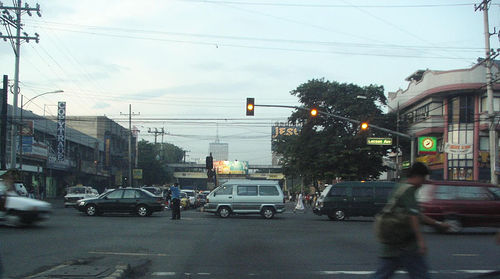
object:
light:
[246, 98, 255, 116]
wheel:
[85, 205, 98, 217]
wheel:
[137, 205, 150, 217]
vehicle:
[76, 187, 166, 216]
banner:
[445, 142, 473, 154]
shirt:
[378, 182, 422, 258]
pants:
[368, 244, 432, 279]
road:
[0, 194, 500, 279]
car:
[202, 180, 284, 220]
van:
[201, 180, 287, 219]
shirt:
[169, 186, 180, 199]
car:
[413, 180, 500, 234]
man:
[292, 190, 306, 213]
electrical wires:
[23, 21, 167, 106]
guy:
[370, 161, 449, 279]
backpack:
[376, 185, 418, 251]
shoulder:
[400, 183, 418, 194]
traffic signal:
[245, 99, 255, 117]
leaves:
[306, 84, 350, 109]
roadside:
[285, 172, 367, 216]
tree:
[273, 77, 395, 185]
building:
[388, 62, 500, 186]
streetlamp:
[18, 90, 65, 171]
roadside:
[11, 150, 109, 212]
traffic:
[63, 177, 461, 221]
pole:
[253, 105, 361, 125]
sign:
[418, 136, 438, 155]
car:
[6, 196, 50, 227]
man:
[164, 182, 181, 220]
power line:
[131, 117, 277, 129]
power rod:
[481, 0, 497, 184]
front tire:
[218, 206, 232, 218]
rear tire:
[260, 207, 276, 218]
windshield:
[321, 185, 333, 197]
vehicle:
[312, 180, 401, 221]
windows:
[237, 186, 279, 196]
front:
[203, 180, 235, 217]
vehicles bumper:
[312, 207, 318, 214]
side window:
[237, 186, 258, 195]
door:
[209, 185, 233, 209]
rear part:
[252, 179, 286, 221]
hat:
[403, 160, 432, 178]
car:
[74, 188, 165, 217]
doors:
[101, 190, 137, 212]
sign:
[55, 101, 66, 162]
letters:
[57, 103, 66, 160]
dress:
[295, 194, 305, 210]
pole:
[128, 104, 132, 188]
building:
[0, 102, 138, 199]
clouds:
[45, 4, 477, 104]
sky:
[1, 0, 500, 144]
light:
[309, 108, 318, 117]